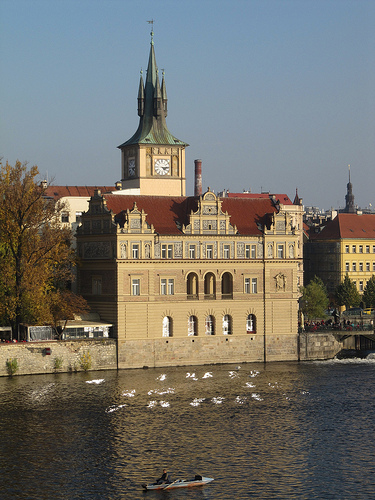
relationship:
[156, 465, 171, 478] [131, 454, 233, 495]
person rowing a boat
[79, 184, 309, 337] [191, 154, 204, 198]
building with chimney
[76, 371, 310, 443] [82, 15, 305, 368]
objects near building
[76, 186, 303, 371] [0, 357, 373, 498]
brick building near water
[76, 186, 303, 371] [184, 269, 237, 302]
brick building has arched openings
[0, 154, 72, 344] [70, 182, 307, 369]
tree near building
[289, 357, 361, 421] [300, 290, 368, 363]
water near bridge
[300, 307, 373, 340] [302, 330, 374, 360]
people on bridge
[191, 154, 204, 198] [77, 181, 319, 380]
chimney above buildings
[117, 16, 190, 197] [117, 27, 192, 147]
clock tower has roof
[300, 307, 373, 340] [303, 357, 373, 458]
people sitting outside near water